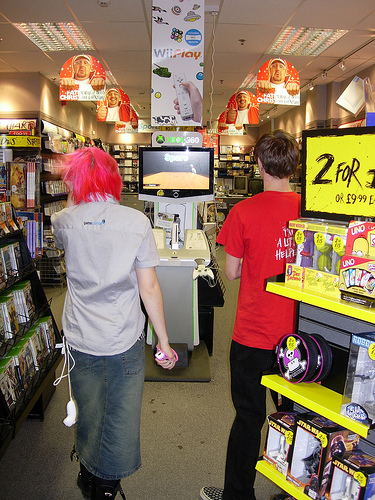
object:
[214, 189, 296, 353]
red shirt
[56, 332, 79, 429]
controller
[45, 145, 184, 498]
person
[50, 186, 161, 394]
clothing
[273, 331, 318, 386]
purse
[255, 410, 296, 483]
star wars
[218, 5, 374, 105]
ceiling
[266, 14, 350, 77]
light fixture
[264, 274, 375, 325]
shelf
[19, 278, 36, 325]
video games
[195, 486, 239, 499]
shoe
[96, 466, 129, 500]
shoe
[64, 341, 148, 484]
skirt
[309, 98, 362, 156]
ground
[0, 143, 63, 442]
shelves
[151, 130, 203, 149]
sign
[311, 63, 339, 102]
ground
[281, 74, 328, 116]
ground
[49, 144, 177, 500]
girl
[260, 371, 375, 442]
shelf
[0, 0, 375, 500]
store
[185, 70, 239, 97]
wall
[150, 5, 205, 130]
banner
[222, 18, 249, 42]
ceiling tile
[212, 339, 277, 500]
pants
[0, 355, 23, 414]
games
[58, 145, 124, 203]
hair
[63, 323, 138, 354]
girl's hips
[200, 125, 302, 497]
man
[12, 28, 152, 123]
ceiling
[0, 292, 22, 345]
video games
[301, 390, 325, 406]
part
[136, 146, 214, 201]
television